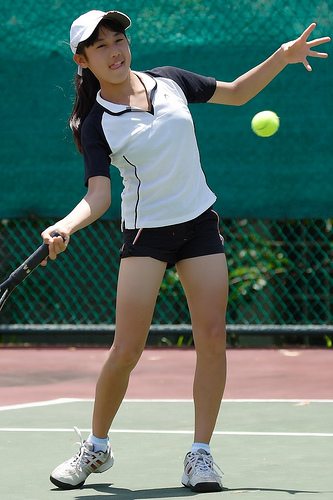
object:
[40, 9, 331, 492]
girl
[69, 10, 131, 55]
hat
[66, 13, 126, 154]
hair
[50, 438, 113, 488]
shoe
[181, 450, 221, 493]
shoe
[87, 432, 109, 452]
sock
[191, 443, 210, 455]
sock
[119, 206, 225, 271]
shorts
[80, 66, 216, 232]
shirt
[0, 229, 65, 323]
racket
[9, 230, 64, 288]
grip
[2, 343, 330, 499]
tennis court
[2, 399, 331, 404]
line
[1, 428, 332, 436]
line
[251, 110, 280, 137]
tennis ball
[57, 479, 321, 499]
shadow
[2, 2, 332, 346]
fence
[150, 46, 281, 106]
arm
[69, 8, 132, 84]
head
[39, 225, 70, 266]
hand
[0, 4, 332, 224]
net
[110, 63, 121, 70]
tongue